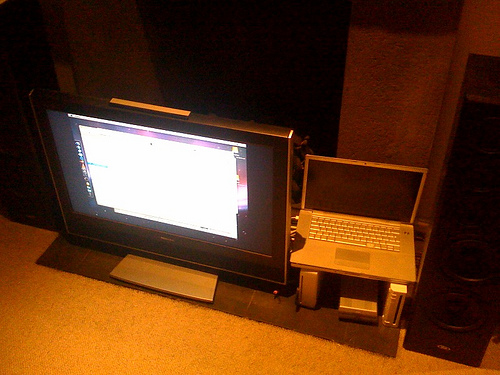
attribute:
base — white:
[76, 270, 244, 271]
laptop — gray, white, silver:
[291, 153, 428, 286]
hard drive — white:
[381, 282, 407, 327]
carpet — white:
[5, 221, 493, 372]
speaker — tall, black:
[402, 51, 496, 368]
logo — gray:
[434, 342, 451, 352]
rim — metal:
[27, 84, 289, 289]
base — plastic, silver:
[108, 251, 220, 304]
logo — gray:
[158, 234, 175, 244]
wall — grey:
[50, 5, 499, 222]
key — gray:
[335, 237, 366, 247]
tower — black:
[401, 53, 498, 368]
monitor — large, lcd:
[45, 108, 273, 261]